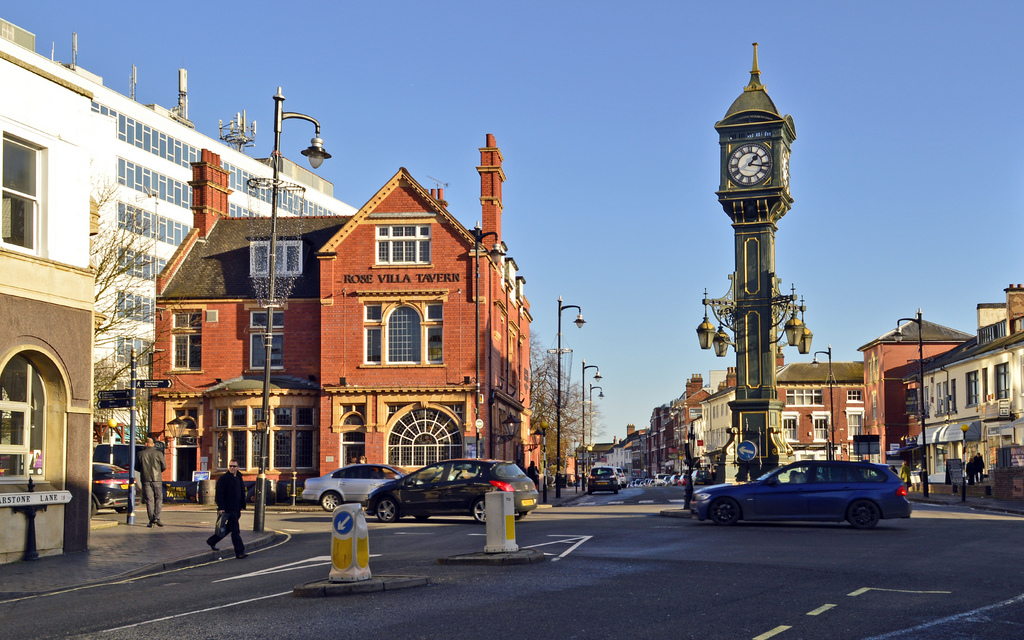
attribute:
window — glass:
[150, 324, 205, 353]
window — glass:
[271, 236, 310, 273]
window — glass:
[377, 219, 403, 272]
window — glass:
[368, 217, 405, 256]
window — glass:
[383, 219, 414, 272]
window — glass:
[405, 217, 427, 280]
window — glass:
[362, 324, 391, 368]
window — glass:
[420, 312, 444, 364]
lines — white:
[764, 543, 916, 604]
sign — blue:
[269, 474, 458, 529]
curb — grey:
[288, 526, 464, 581]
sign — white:
[0, 480, 104, 543]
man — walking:
[203, 456, 262, 560]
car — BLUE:
[676, 452, 921, 530]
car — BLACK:
[361, 441, 552, 534]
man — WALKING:
[200, 461, 274, 572]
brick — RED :
[453, 314, 464, 353]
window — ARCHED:
[363, 301, 435, 369]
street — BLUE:
[427, 515, 992, 636]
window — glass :
[376, 301, 433, 373]